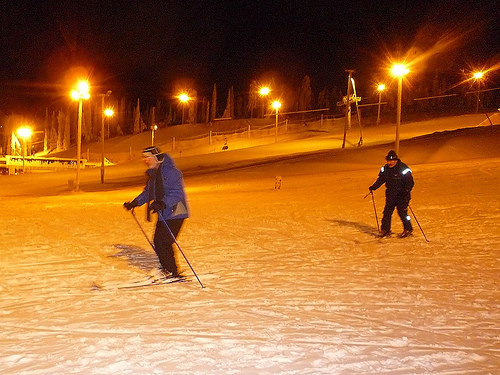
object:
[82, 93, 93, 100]
light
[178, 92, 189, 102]
light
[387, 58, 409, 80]
light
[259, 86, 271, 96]
light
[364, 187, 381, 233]
ski pole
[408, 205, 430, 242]
ski pole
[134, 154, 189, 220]
coat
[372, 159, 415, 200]
coat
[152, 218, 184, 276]
snow pants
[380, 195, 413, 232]
snow pants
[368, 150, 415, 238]
person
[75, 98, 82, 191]
pole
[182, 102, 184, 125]
pole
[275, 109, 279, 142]
pole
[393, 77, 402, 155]
pole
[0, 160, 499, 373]
downhill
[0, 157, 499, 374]
snow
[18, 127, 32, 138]
light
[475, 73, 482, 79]
light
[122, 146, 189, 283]
people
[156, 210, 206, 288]
ski pole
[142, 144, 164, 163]
hat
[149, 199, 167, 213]
gloves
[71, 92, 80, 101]
lamp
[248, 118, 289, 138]
fences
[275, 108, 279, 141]
lamp post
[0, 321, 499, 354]
tracks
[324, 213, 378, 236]
shadow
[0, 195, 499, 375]
ground